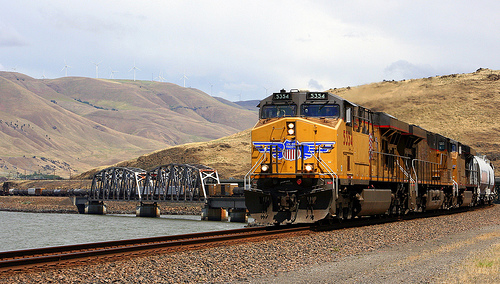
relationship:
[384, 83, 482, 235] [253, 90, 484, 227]
person boarding train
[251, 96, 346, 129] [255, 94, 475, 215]
windows on train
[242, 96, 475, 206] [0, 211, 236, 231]
train next to water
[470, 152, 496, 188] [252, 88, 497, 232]
water tank on train